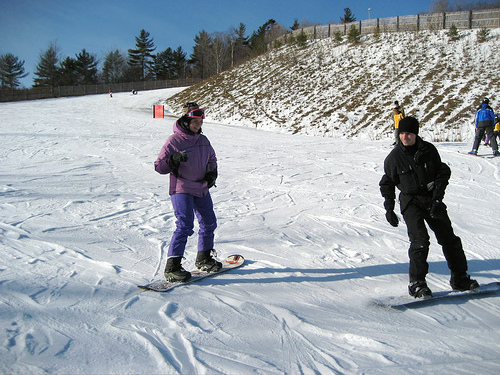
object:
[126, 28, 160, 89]
trees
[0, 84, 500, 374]
snow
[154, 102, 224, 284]
woman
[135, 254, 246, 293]
snowboard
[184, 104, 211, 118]
goggles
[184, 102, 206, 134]
head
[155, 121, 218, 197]
jacket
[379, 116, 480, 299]
man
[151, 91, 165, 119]
rise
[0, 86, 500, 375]
ground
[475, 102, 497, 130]
jacket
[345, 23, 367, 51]
trees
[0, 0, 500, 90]
sky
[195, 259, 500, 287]
shade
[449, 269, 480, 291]
edge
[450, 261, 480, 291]
shoe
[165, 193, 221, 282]
jeans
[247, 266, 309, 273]
edge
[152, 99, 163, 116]
sign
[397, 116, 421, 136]
cap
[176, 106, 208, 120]
goggle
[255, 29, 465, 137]
hill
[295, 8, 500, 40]
fence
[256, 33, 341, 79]
green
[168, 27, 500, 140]
slope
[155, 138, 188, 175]
arm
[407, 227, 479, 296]
boots